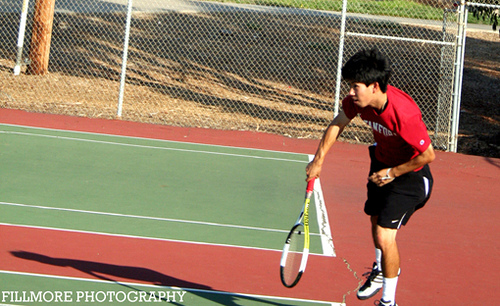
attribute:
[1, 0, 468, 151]
fence — chain link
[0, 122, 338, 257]
square patch — green and white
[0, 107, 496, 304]
tennis court — white, green, gated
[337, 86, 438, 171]
shirt — red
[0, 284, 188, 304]
lettering — white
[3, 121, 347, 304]
tennis court — green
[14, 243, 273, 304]
shadow — man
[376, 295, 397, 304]
shoe — tennis, black, white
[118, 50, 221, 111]
chain link — metal, tall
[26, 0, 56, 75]
pole — electric, wooden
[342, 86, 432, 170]
t shirt — red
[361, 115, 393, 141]
letters — white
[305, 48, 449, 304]
person — playing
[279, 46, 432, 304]
kid — playing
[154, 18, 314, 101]
fence — chain link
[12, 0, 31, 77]
pole — white, metal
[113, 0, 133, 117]
pole — metal, white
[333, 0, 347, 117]
pole — metal, white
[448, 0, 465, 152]
pole — metal, white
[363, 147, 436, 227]
shorts — athletic, black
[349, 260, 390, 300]
shoe — white, black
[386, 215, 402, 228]
logo — Nike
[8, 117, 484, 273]
area — red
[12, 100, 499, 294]
court — red and green